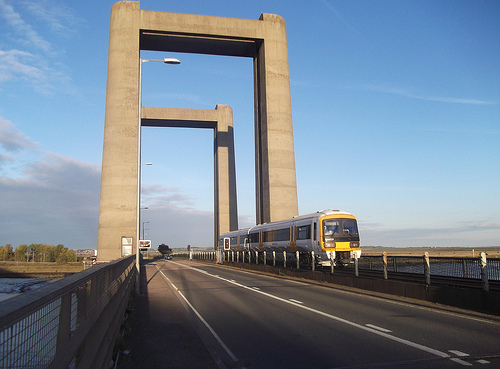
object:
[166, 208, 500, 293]
railroad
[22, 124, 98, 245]
cloud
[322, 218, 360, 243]
windshield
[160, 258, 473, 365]
line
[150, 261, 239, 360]
white line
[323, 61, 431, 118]
clouds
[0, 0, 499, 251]
sky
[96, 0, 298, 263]
arch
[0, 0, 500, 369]
bridge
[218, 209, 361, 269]
train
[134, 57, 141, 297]
pole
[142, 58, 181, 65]
light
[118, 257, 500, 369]
highway